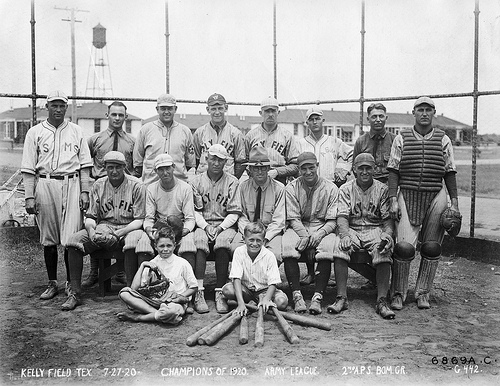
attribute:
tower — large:
[87, 23, 115, 106]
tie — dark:
[254, 186, 261, 221]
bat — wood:
[257, 307, 264, 347]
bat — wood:
[268, 309, 303, 346]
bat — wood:
[238, 317, 250, 347]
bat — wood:
[249, 301, 332, 334]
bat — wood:
[184, 308, 236, 348]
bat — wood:
[205, 310, 238, 347]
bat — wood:
[200, 312, 233, 345]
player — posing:
[397, 98, 461, 310]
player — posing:
[24, 95, 93, 307]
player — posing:
[91, 148, 147, 297]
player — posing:
[142, 152, 196, 292]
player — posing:
[138, 99, 200, 181]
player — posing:
[193, 96, 247, 177]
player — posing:
[246, 103, 288, 172]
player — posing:
[293, 112, 356, 188]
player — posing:
[281, 158, 337, 312]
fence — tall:
[2, 0, 499, 261]